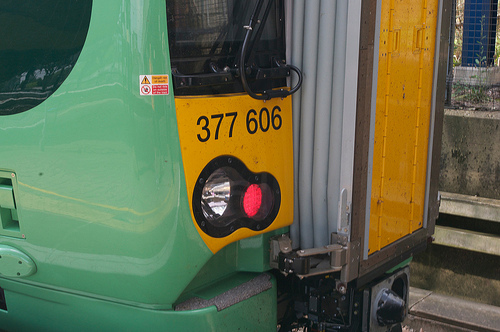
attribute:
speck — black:
[32, 161, 52, 189]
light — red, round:
[242, 185, 269, 220]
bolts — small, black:
[16, 259, 23, 278]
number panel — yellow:
[173, 97, 295, 243]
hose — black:
[234, 0, 312, 112]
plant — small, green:
[470, 12, 491, 107]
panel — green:
[1, 2, 283, 329]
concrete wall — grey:
[439, 110, 499, 256]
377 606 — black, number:
[194, 100, 288, 140]